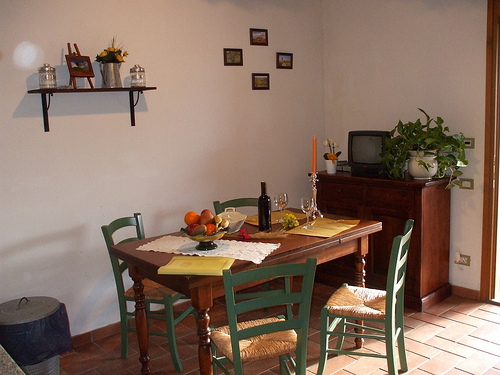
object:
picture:
[248, 27, 270, 47]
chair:
[314, 219, 416, 375]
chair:
[100, 213, 202, 372]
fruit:
[191, 223, 207, 235]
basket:
[176, 224, 228, 251]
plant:
[376, 107, 469, 191]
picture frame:
[251, 72, 272, 92]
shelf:
[24, 87, 157, 96]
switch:
[459, 179, 476, 190]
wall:
[323, 0, 487, 298]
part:
[326, 0, 482, 86]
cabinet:
[307, 171, 451, 315]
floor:
[60, 275, 500, 374]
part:
[404, 291, 497, 372]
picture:
[221, 47, 244, 67]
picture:
[274, 52, 296, 70]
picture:
[251, 72, 271, 91]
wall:
[0, 1, 320, 351]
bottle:
[257, 181, 274, 235]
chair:
[208, 258, 316, 375]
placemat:
[134, 234, 279, 264]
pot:
[407, 150, 441, 182]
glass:
[297, 198, 313, 230]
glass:
[272, 190, 288, 222]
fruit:
[183, 211, 201, 224]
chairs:
[211, 197, 257, 218]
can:
[0, 295, 72, 368]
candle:
[310, 137, 317, 174]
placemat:
[283, 215, 360, 239]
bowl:
[214, 205, 248, 234]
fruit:
[199, 209, 214, 227]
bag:
[1, 314, 69, 355]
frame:
[247, 28, 269, 48]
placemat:
[155, 255, 235, 276]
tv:
[344, 130, 391, 179]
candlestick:
[302, 171, 325, 221]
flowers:
[114, 54, 123, 63]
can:
[99, 62, 124, 88]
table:
[107, 207, 383, 374]